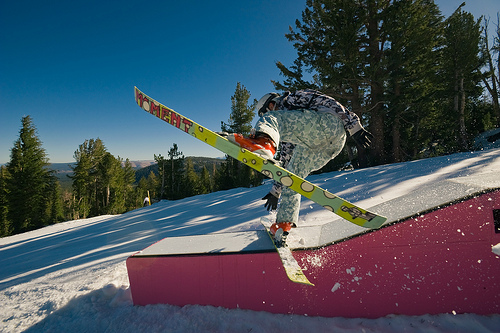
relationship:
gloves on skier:
[338, 117, 390, 163] [200, 71, 412, 282]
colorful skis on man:
[132, 82, 390, 230] [130, 85, 368, 262]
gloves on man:
[343, 118, 381, 151] [185, 52, 430, 293]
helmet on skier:
[245, 88, 310, 128] [138, 73, 379, 239]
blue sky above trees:
[0, 0, 500, 162] [35, 109, 282, 250]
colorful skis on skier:
[132, 82, 390, 230] [181, 90, 373, 274]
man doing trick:
[268, 90, 347, 240] [125, 85, 492, 316]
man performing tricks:
[219, 79, 380, 250] [121, 84, 481, 330]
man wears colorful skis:
[219, 79, 380, 250] [132, 82, 390, 230]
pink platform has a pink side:
[122, 169, 500, 320] [121, 248, 429, 313]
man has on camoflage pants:
[219, 79, 380, 250] [251, 108, 351, 229]